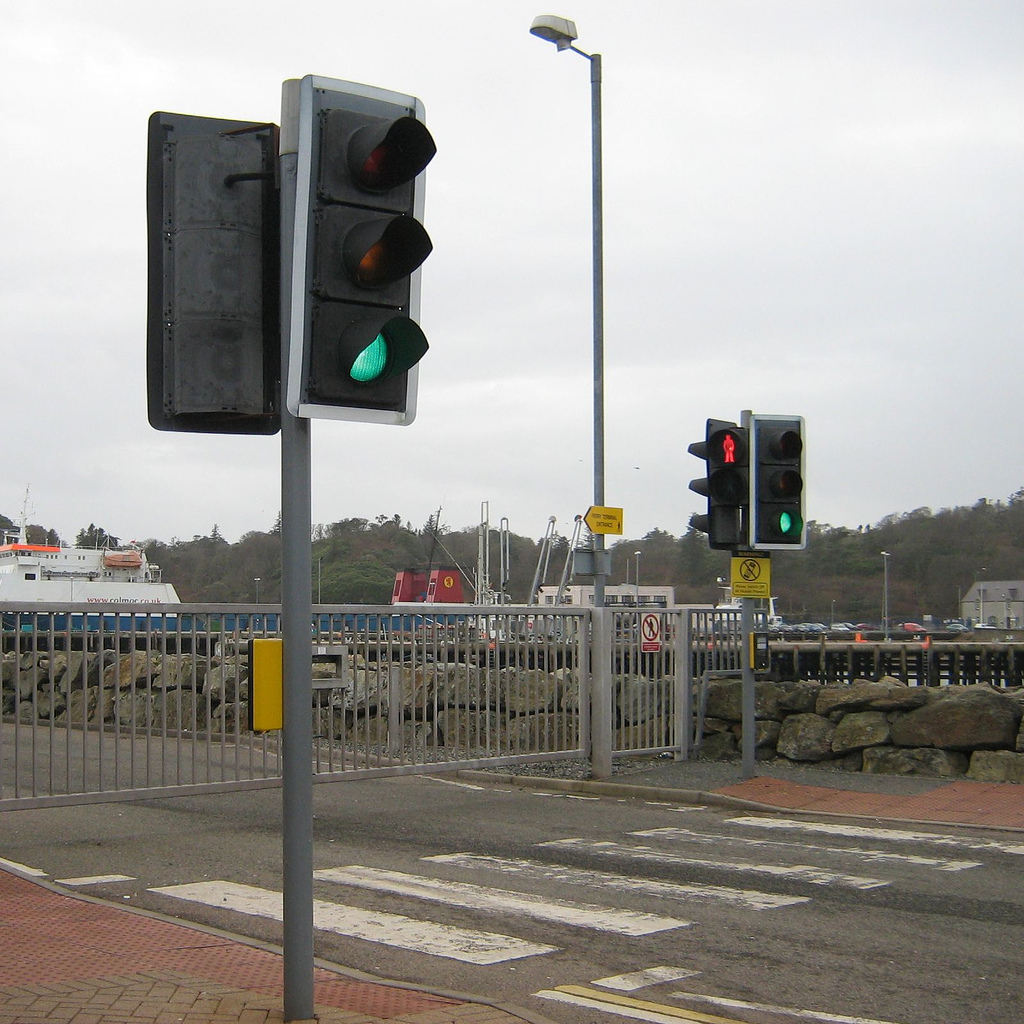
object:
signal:
[748, 409, 807, 551]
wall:
[0, 646, 1024, 774]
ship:
[0, 540, 188, 612]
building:
[960, 580, 1024, 633]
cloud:
[622, 0, 1023, 339]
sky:
[3, 6, 1024, 527]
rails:
[0, 598, 761, 812]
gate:
[603, 602, 689, 779]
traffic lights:
[270, 71, 438, 437]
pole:
[739, 408, 758, 781]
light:
[722, 435, 735, 464]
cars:
[830, 621, 851, 636]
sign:
[729, 550, 772, 599]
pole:
[277, 77, 329, 1019]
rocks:
[882, 684, 1021, 754]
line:
[719, 812, 1024, 859]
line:
[533, 830, 892, 892]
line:
[144, 880, 561, 967]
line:
[419, 841, 814, 915]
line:
[310, 864, 699, 939]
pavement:
[145, 808, 993, 967]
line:
[528, 977, 753, 1024]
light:
[356, 241, 389, 284]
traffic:
[686, 416, 751, 547]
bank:
[146, 108, 283, 437]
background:
[0, 478, 1024, 805]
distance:
[904, 513, 1019, 758]